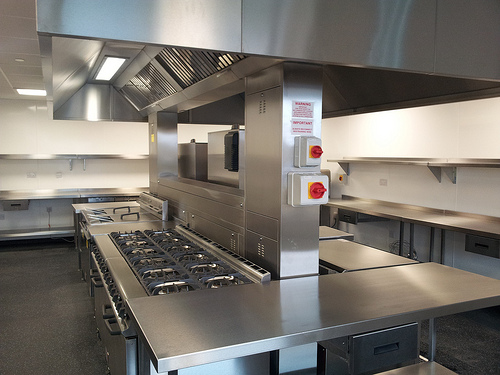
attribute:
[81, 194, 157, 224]
handles — black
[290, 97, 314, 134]
warning label — red, white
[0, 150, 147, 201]
counters — white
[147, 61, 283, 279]
wall — steel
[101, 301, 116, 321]
handle — black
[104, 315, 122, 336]
handle — black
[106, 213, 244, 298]
stove units — multiple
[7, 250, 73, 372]
floor — black , tile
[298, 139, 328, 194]
buttons — orange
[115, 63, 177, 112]
vent — large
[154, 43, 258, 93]
vent — large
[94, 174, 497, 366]
counter — steel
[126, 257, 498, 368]
countertop — shiny, new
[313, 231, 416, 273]
countertop — shiny, new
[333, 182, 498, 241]
countertop — shiny, new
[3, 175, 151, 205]
countertop — shiny, new